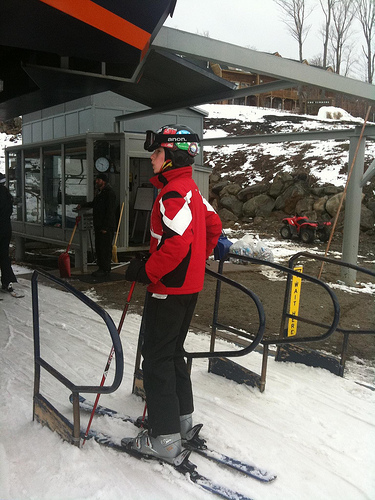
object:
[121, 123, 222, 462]
man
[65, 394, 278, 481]
skis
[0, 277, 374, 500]
snow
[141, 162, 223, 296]
jacket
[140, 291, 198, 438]
pants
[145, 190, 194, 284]
patches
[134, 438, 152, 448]
ski strap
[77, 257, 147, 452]
ski pole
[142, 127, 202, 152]
goggles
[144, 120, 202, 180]
head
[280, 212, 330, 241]
atv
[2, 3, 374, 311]
background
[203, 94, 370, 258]
hill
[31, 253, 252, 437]
entrance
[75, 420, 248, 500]
ski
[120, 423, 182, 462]
ski boots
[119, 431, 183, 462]
feet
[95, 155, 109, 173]
clock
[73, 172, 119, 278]
man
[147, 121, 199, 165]
helmet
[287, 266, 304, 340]
sign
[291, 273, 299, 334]
wait here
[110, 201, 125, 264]
broom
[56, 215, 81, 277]
shovel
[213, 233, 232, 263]
trashcan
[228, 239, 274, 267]
trash bags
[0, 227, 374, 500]
ground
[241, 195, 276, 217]
rocks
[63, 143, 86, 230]
windows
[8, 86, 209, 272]
building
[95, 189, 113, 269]
black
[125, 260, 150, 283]
gloves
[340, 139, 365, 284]
pole